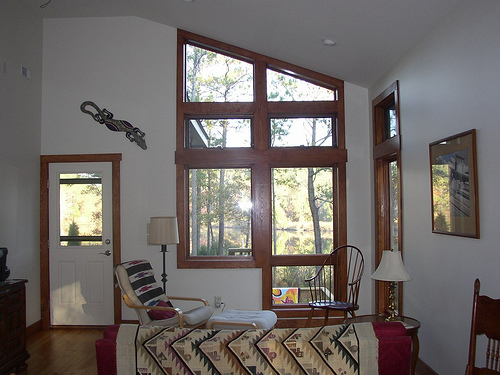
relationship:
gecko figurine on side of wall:
[79, 98, 148, 151] [39, 16, 371, 327]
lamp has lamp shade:
[370, 249, 409, 320] [370, 249, 412, 283]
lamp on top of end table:
[370, 249, 409, 320] [342, 311, 420, 374]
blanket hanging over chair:
[110, 259, 176, 321] [114, 255, 213, 328]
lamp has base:
[370, 249, 409, 320] [377, 283, 403, 321]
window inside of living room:
[184, 38, 339, 314] [0, 1, 499, 373]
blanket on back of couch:
[114, 321, 379, 374] [94, 321, 412, 373]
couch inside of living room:
[94, 321, 412, 373] [0, 1, 499, 373]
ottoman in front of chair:
[207, 305, 277, 331] [114, 255, 213, 328]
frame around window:
[173, 25, 347, 321] [184, 38, 339, 314]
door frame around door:
[37, 151, 123, 329] [49, 160, 114, 327]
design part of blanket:
[133, 324, 359, 374] [114, 321, 379, 374]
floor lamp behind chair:
[147, 213, 180, 295] [114, 255, 213, 328]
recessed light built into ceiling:
[321, 33, 336, 49] [26, 1, 462, 91]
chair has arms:
[304, 243, 366, 327] [305, 274, 362, 288]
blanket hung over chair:
[110, 259, 176, 321] [114, 255, 213, 328]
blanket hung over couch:
[114, 321, 379, 374] [94, 321, 412, 373]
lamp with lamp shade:
[370, 249, 409, 320] [370, 249, 412, 283]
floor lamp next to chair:
[147, 213, 180, 295] [114, 255, 213, 328]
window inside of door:
[56, 172, 103, 248] [49, 160, 114, 327]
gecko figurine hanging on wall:
[79, 98, 148, 151] [39, 16, 371, 327]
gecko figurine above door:
[79, 98, 148, 151] [49, 160, 114, 327]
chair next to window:
[304, 243, 366, 327] [184, 38, 339, 314]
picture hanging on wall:
[427, 126, 481, 241] [370, 3, 498, 373]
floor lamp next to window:
[147, 213, 180, 295] [184, 38, 339, 314]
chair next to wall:
[114, 255, 213, 328] [39, 16, 371, 327]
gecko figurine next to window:
[79, 98, 148, 151] [184, 38, 339, 314]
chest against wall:
[2, 276, 32, 374] [0, 3, 44, 333]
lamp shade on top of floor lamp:
[145, 213, 180, 246] [147, 213, 180, 295]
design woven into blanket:
[133, 324, 359, 374] [114, 321, 379, 374]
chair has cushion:
[114, 255, 213, 328] [115, 259, 212, 324]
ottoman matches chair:
[207, 305, 277, 331] [114, 255, 213, 328]